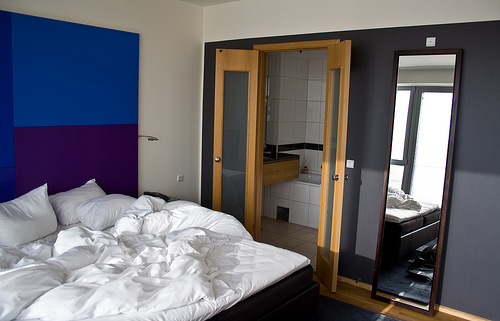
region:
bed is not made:
[1, 183, 261, 315]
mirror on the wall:
[378, 129, 477, 315]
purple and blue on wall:
[24, 56, 133, 173]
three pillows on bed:
[9, 188, 192, 263]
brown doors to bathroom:
[211, 43, 350, 226]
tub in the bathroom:
[281, 136, 333, 217]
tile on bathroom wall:
[288, 113, 324, 151]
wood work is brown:
[440, 300, 449, 313]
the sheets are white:
[125, 229, 301, 306]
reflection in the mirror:
[376, 124, 495, 184]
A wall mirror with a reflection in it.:
[363, 35, 468, 317]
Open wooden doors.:
[208, 33, 358, 291]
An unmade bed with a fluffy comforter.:
[1, 173, 330, 317]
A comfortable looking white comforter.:
[0, 177, 320, 319]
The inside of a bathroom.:
[257, 43, 324, 270]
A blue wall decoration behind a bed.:
[0, 10, 152, 200]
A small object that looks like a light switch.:
[341, 156, 358, 173]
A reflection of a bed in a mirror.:
[381, 183, 441, 264]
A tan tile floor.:
[256, 210, 321, 275]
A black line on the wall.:
[268, 131, 327, 171]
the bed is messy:
[2, 181, 298, 311]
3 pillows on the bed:
[0, 175, 164, 234]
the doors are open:
[191, 17, 350, 283]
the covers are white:
[35, 186, 307, 314]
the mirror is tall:
[344, 34, 454, 307]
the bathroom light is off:
[259, 52, 345, 256]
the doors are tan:
[195, 18, 346, 280]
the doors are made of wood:
[180, 28, 360, 291]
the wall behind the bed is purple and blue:
[2, 16, 160, 202]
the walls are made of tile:
[258, 60, 330, 223]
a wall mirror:
[368, 47, 461, 317]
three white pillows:
[0, 176, 136, 246]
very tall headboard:
[0, 10, 135, 197]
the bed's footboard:
[205, 261, 310, 316]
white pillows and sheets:
[0, 176, 307, 316]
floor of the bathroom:
[257, 216, 317, 266]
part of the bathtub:
[262, 165, 317, 225]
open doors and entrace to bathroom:
[210, 36, 350, 291]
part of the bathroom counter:
[265, 150, 300, 181]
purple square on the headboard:
[15, 125, 138, 200]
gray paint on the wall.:
[460, 202, 486, 265]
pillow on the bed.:
[9, 198, 45, 232]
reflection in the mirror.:
[412, 129, 435, 213]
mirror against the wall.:
[377, 273, 424, 285]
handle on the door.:
[211, 154, 218, 165]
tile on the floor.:
[284, 229, 307, 249]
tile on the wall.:
[281, 82, 296, 123]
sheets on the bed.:
[239, 257, 289, 279]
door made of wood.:
[225, 53, 254, 62]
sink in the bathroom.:
[267, 158, 292, 175]